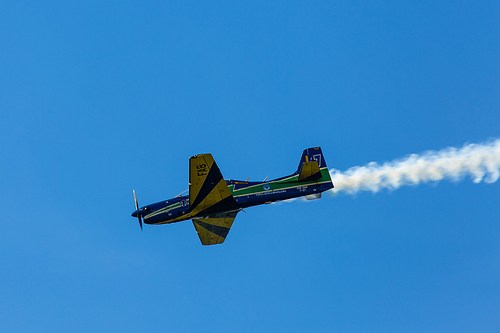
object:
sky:
[0, 1, 499, 332]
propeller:
[130, 189, 145, 234]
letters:
[197, 161, 208, 178]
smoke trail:
[330, 136, 500, 201]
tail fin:
[296, 146, 330, 173]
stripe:
[145, 158, 240, 243]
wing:
[187, 152, 233, 208]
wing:
[189, 209, 239, 247]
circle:
[262, 183, 270, 191]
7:
[312, 153, 322, 168]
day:
[1, 0, 500, 332]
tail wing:
[298, 160, 326, 185]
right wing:
[190, 209, 239, 248]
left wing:
[187, 153, 235, 208]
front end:
[141, 196, 191, 226]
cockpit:
[171, 178, 244, 221]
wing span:
[187, 153, 239, 245]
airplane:
[131, 145, 335, 246]